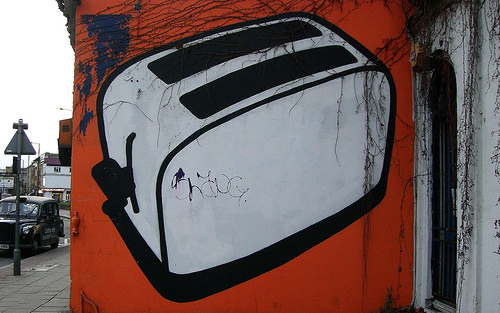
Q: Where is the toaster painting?
A: On the wall.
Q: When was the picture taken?
A: Daytime.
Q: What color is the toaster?
A: Black and white.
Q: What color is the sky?
A: Gray.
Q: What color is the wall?
A: Red.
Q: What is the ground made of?
A: Cement.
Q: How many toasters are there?
A: One.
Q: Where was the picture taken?
A: On the sidewalk.